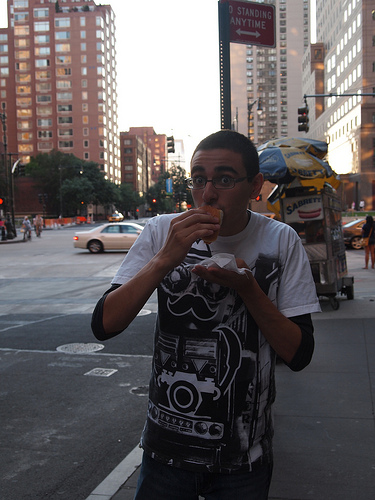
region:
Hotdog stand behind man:
[252, 133, 353, 304]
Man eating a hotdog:
[90, 122, 317, 499]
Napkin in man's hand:
[194, 242, 251, 286]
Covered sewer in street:
[50, 328, 113, 375]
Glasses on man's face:
[172, 166, 267, 195]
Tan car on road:
[67, 211, 140, 258]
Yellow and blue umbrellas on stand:
[255, 128, 338, 218]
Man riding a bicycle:
[11, 207, 34, 243]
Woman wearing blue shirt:
[354, 209, 373, 271]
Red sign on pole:
[207, 1, 283, 54]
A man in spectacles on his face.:
[181, 170, 259, 194]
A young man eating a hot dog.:
[88, 128, 321, 498]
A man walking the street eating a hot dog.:
[87, 128, 321, 499]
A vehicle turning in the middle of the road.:
[61, 210, 139, 252]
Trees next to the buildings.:
[21, 150, 183, 216]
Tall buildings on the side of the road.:
[0, 0, 165, 219]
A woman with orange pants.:
[358, 212, 374, 269]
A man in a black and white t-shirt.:
[89, 122, 323, 473]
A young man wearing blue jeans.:
[130, 437, 292, 499]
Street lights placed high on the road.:
[296, 83, 373, 141]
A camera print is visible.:
[146, 348, 215, 449]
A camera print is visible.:
[116, 317, 249, 489]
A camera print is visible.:
[95, 263, 207, 408]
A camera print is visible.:
[105, 353, 197, 464]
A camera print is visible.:
[166, 376, 253, 497]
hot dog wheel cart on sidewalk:
[253, 136, 356, 310]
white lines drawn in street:
[91, 464, 139, 497]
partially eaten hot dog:
[189, 199, 226, 241]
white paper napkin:
[189, 251, 256, 278]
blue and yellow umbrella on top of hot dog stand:
[250, 131, 335, 188]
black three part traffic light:
[290, 95, 313, 134]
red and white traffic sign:
[223, 0, 280, 53]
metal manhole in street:
[50, 339, 106, 358]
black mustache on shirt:
[159, 290, 220, 321]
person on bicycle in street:
[17, 215, 34, 242]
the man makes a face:
[80, 96, 360, 346]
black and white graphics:
[143, 339, 297, 452]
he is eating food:
[137, 118, 333, 320]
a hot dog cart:
[250, 116, 367, 341]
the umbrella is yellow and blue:
[247, 108, 355, 307]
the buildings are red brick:
[37, 85, 195, 215]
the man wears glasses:
[128, 149, 281, 290]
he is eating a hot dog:
[121, 159, 326, 326]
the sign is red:
[187, 1, 301, 63]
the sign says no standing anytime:
[212, 11, 327, 102]